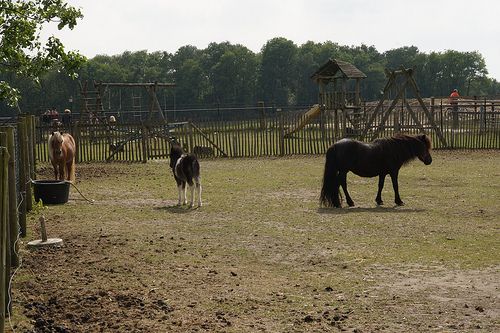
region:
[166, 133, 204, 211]
small black and white pony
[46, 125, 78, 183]
brown horse with a blonde mane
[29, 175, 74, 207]
watering trough for horses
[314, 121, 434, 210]
beautiful dark colored horse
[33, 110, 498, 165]
fence around horse area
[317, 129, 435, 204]
dark brown colored horse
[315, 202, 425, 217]
a dark shadow on the ground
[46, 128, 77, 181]
a brown horse with a blonde main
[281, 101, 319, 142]
a yellow slide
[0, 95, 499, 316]
a wooden fence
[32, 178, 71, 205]
a round watering container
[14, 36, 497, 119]
green trees are in the background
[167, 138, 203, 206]
a horse with white legs and feet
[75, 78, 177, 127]
wooden climbing area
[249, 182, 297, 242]
Grass in the field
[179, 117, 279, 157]
A wooden fence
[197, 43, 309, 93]
Trees in the photo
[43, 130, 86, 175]
Brown and white horse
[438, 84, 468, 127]
A man in the background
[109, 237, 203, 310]
Bare ground in the side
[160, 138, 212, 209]
Black and white horse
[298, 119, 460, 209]
a horse is brown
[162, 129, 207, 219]
a horse in a fenced in area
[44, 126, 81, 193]
a horse in a fenced in area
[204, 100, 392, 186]
a brown wooden fence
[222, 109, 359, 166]
a tall wooden fence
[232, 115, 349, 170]
a tall brown fence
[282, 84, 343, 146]
a yellow slide is outside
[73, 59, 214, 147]
a swing set outside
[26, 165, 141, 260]
a bucket is outside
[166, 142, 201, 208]
A dark brown and white horse.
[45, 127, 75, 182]
A brown and white horse.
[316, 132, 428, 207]
A long haired black horse.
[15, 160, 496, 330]
A grass and mud field inside a fence.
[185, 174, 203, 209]
Back two legs of the black and white horse.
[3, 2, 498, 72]
A mostly white sky.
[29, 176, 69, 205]
Large black round tub in front of a brown horse.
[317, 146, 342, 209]
Long black horse tail.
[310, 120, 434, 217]
black horse with long hairy tail in pasture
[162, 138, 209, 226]
small brown and white horse in pasture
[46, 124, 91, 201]
brown horse with white mane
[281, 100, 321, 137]
A yellow slide.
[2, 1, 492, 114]
Green leafy trees.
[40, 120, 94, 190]
A brown horse.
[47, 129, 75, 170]
brown horse in enclosure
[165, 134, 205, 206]
brown horse in enclosure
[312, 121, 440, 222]
brown horse in enclosure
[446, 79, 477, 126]
person wearing orange top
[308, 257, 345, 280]
short green and brown grass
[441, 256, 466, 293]
short green and brown grass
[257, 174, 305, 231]
short green and brown grass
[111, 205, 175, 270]
short green and brown grass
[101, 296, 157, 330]
short green and brown grass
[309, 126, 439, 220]
the pony has long tail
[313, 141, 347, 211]
tail of pony is long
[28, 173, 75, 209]
a hose over a black container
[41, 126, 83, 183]
the pony is brown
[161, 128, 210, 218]
the legs of pony are white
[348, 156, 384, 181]
the belly is bulky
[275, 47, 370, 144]
a playground behind the ponies